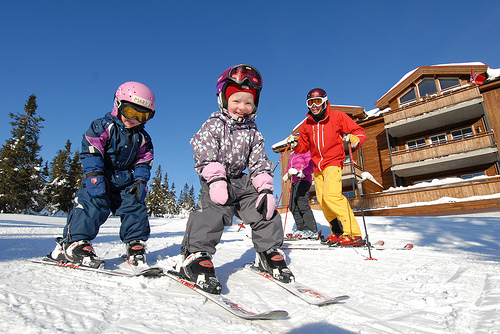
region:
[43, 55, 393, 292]
people skiing on the snow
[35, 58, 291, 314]
two toddlers skiing on the snow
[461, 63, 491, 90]
flag on the house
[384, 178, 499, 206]
balcony on the house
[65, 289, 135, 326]
tracks in the snow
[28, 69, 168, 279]
toddler wearing a snowsuit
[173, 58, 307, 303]
toddler wearing ski pants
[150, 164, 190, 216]
snow covered pine trees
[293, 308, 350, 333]
shadow in the snow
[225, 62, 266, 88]
goggles on the helmet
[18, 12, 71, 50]
white clouds in blue sky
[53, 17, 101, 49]
white clouds in blue sky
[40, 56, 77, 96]
white clouds in blue sky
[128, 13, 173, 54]
white clouds in blue sky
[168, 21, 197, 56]
white clouds in blue sky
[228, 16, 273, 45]
white clouds in blue sky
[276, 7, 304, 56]
white clouds in blue sky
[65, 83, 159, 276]
child skier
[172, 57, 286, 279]
child skier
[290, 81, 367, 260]
skier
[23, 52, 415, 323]
People wearing ski's on the snow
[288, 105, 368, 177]
Red jacket worn by man on ski's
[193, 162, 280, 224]
Pink gloves worn by child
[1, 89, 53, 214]
Green pine tree at the background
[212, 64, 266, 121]
Child wearing purple helmet smiling at the camera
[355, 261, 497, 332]
Ski marks on the snow next to the child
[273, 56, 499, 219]
Brown structure behind the man on ski's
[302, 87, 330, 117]
Red helmet worn by man on skis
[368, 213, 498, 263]
Shadow of an object on the snow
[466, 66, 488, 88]
Flag on top side of the balcony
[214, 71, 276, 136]
face of the person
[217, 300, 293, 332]
a skating machine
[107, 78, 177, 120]
helmet wearing by boy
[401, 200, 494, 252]
shadow of the tree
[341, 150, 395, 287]
a stick holding by person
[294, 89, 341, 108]
spects wearing by person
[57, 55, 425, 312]
a group of people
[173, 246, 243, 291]
shoe of the person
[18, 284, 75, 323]
riddle on the ice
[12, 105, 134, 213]
a group of trees on back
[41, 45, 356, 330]
Two small kids in the foreground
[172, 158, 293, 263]
Young kid is wearing gray pants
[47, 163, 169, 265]
Young kid is wearing blue pants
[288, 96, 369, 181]
Person is wearing a red jacket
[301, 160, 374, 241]
Person is wearing yellow pants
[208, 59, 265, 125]
Young kid's goggles is on their head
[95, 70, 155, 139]
Young girl is wearing a helmet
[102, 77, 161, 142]
The helmet is pink in color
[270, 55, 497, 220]
A building in the background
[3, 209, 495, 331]
Snow is covering the ground